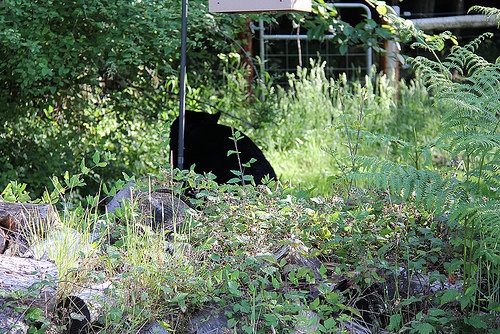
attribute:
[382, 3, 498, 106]
post — grey 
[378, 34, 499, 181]
plant — green 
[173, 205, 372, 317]
leaves — green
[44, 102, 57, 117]
leaf — green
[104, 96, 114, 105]
leaf — green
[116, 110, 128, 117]
leaf — green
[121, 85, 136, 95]
leaf — green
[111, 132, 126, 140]
leaf — green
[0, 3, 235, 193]
green leaves — green 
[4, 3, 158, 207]
leaves — green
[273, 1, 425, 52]
leaves — green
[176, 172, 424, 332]
leaves — green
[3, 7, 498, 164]
trees — brown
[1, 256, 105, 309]
logs — gray 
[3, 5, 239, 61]
leaves — green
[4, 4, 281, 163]
trees — brown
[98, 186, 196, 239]
white stone — white 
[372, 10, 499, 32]
railing — silver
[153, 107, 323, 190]
cat — black 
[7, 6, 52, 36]
leaves — green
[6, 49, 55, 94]
leaves — green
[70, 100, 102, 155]
leaves — green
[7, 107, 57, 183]
leaves — green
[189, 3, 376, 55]
leaves — green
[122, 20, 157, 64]
leaves — green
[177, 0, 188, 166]
pole — small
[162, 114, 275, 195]
bear — black 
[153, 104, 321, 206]
cat — black  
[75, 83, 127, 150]
leaves — green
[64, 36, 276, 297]
trees — brown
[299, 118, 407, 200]
grasses — tall 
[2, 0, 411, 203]
tree — brown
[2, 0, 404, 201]
leaves — green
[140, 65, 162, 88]
trees — brown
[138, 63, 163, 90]
tree — brown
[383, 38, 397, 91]
tree — brown